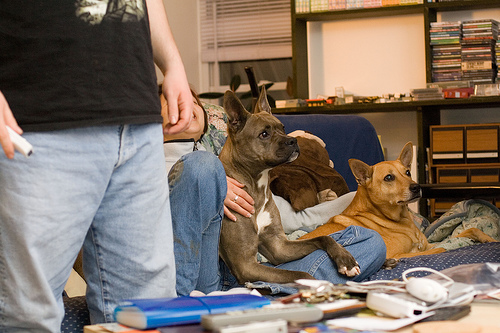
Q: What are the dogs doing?
A: Sitting.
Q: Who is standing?
A: Person in the black shirt.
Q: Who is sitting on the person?
A: The dog.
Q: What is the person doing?
A: Standing.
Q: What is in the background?
A: A window.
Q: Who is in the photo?
A: A person.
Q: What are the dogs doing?
A: Laying down.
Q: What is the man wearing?
A: A shirt.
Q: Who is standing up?
A: The man.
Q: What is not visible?
A: Top part of man.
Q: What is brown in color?
A: The dogs.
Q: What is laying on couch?
A: A tan dog.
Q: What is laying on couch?
A: Brown dog.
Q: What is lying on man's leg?
A: Brown dog.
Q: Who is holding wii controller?
A: A man.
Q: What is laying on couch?
A: Two dogs.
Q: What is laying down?
A: Tan dog.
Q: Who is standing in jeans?
A: A man.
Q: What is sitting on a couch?
A: Two dogs.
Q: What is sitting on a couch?
A: Tan dog.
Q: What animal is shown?
A: Dogs.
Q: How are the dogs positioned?
A: Sitting down.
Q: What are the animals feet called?
A: Paws.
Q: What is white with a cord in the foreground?
A: A computer mouse.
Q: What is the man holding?
A: A controller.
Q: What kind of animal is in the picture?
A: Dogs.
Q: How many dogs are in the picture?
A: Two.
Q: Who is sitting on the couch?
A: A woman.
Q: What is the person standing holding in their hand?
A: Remote control.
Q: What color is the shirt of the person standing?
A: Black.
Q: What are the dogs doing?
A: Sitting.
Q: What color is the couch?
A: Blue.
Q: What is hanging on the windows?
A: Blinds.